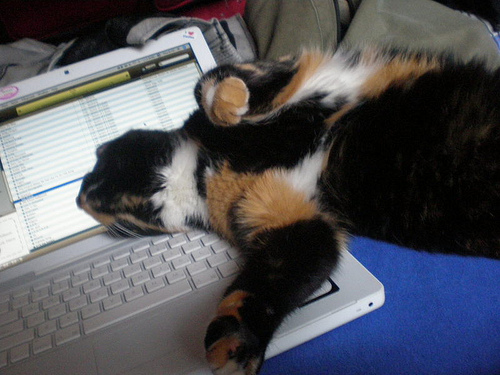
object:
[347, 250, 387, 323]
edge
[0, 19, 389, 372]
laptop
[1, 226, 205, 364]
key pad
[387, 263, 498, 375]
top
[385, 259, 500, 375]
table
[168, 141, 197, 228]
white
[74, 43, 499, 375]
cat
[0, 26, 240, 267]
screen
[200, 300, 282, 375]
paws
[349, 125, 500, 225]
back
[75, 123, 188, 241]
face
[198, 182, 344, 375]
leg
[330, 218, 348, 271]
edge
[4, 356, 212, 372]
edge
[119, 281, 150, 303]
button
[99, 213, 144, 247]
whisker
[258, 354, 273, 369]
edge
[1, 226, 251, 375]
keyboard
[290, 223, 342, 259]
knee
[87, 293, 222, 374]
trackpad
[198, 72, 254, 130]
paw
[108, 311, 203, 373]
air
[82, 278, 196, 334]
spacebar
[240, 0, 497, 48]
clothes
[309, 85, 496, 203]
belly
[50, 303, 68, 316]
key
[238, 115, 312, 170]
chest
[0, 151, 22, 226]
lens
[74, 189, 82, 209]
nose